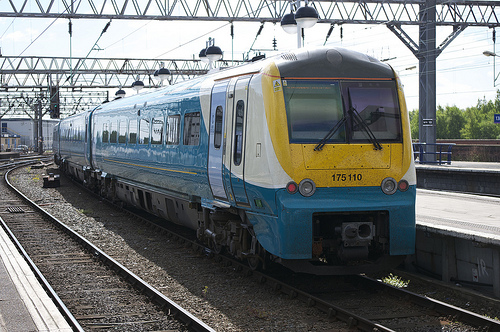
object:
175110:
[326, 169, 364, 183]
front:
[252, 50, 409, 266]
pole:
[413, 9, 435, 163]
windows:
[95, 112, 209, 150]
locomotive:
[50, 14, 445, 301]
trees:
[406, 100, 497, 145]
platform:
[412, 126, 495, 246]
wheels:
[189, 212, 278, 276]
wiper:
[310, 109, 353, 153]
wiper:
[346, 103, 388, 150]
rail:
[3, 189, 216, 329]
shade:
[47, 166, 493, 329]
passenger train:
[49, 43, 420, 283]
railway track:
[246, 260, 498, 330]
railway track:
[1, 152, 220, 330]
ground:
[162, 261, 234, 317]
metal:
[339, 203, 364, 243]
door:
[228, 70, 258, 210]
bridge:
[139, 3, 217, 14]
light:
[398, 176, 410, 197]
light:
[377, 175, 400, 200]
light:
[298, 177, 318, 200]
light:
[282, 176, 302, 195]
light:
[279, 6, 321, 33]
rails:
[13, 127, 180, 319]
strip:
[110, 159, 199, 180]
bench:
[421, 136, 446, 166]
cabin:
[225, 44, 415, 264]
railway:
[420, 140, 476, 192]